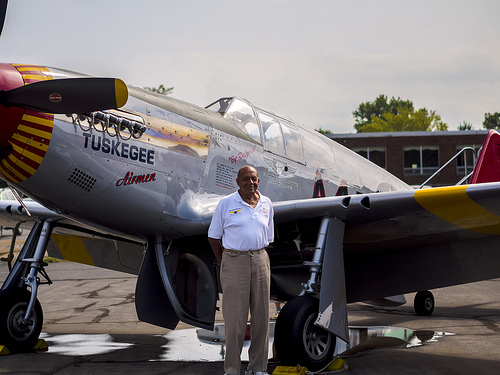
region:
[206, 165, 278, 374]
a man standing in front of a plane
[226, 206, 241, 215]
yellow design on a man's shirt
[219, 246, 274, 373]
tan pants on a man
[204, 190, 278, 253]
white shirt on a man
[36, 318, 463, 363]
large puddle of water on a ground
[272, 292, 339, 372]
black and silver wheels of a jet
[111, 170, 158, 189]
red print on a jet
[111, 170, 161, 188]
red print on a jet reading Airmen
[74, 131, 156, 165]
blue print on a jet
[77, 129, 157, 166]
blue print on a jet reading Tuskegee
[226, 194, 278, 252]
Man wearing white shirt.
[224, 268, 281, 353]
Man wearing tan pants.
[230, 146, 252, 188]
Man in front of plane is bald.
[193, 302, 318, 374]
Man is standing in front of airplane.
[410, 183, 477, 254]
Yellow stripe on side of wing.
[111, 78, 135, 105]
Yellow tip on propeller.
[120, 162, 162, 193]
Red writing on side of plane.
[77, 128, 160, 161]
Dark lettering on side of plane.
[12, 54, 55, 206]
Red and yellow stripes on front of plane.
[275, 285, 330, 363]
Black tire on plane.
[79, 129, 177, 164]
black words on the side of plane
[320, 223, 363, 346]
silver flaps on wheel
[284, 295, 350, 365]
black wheel on plane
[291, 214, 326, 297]
silver frame on wheel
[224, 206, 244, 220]
yellow and blue logo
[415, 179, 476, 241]
yellow paint on wing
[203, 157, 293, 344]
man standing in front of plane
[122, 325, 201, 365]
puddle of water on the ground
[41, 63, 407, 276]
vintage silver war plane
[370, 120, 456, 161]
brown building behind plane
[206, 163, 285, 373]
a man standing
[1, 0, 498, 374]
a man standing in front of an airplane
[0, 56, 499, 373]
a old airplane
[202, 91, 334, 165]
airplane cockpit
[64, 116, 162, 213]
name on the side of the airplane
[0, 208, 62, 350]
front wheel of the airplane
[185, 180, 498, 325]
gray and yellow airplane wing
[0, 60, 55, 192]
red and yellow airplane nose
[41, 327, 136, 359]
a puddle on the ground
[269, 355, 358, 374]
yellow wheel brake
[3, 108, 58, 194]
red and yellow stripes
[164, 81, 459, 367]
man in front of an airplane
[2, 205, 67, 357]
front landing gear of an airplane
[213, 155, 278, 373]
man with white shirt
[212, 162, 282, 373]
man in tan pants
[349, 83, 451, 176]
tree tops behind building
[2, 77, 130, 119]
black and yellow airplane propeller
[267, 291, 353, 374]
yellow sandbag around airplane wheel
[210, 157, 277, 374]
man with bald head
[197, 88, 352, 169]
clear cockpit of an airplane